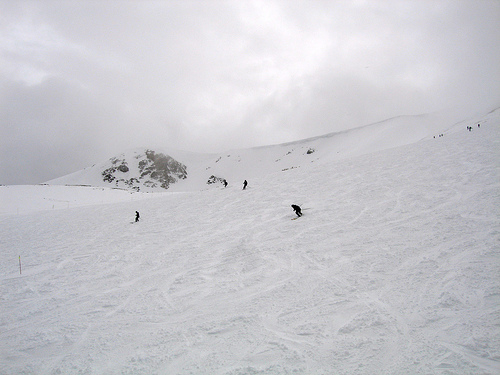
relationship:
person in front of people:
[289, 200, 306, 220] [127, 210, 143, 222]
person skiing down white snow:
[289, 200, 306, 220] [298, 220, 310, 231]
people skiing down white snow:
[127, 210, 143, 222] [298, 220, 310, 231]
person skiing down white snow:
[242, 178, 249, 192] [298, 220, 310, 231]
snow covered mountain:
[220, 239, 242, 254] [131, 154, 191, 186]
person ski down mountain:
[289, 200, 306, 220] [131, 154, 191, 186]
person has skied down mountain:
[289, 200, 306, 220] [131, 154, 191, 186]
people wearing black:
[127, 210, 143, 222] [133, 208, 147, 217]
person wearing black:
[242, 178, 249, 192] [242, 176, 249, 193]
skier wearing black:
[219, 176, 231, 188] [242, 176, 249, 193]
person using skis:
[289, 200, 306, 220] [293, 211, 306, 220]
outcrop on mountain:
[106, 150, 198, 184] [131, 154, 191, 186]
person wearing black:
[289, 200, 306, 220] [290, 201, 304, 216]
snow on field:
[220, 239, 242, 254] [183, 223, 284, 252]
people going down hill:
[127, 210, 143, 222] [92, 265, 191, 317]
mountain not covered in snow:
[131, 154, 191, 186] [220, 239, 242, 254]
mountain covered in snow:
[0, 103, 499, 281] [220, 239, 242, 254]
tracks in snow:
[385, 177, 421, 205] [220, 239, 242, 254]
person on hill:
[289, 200, 306, 220] [92, 265, 191, 317]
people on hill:
[127, 210, 143, 222] [92, 265, 191, 317]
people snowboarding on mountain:
[127, 210, 143, 222] [131, 154, 191, 186]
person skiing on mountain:
[289, 200, 306, 220] [131, 154, 191, 186]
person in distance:
[242, 178, 249, 192] [242, 178, 251, 188]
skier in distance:
[219, 176, 231, 188] [221, 177, 230, 187]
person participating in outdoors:
[289, 200, 306, 220] [289, 201, 303, 217]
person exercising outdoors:
[289, 200, 306, 220] [289, 201, 300, 216]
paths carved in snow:
[103, 230, 123, 244] [220, 239, 242, 254]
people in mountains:
[127, 210, 143, 222] [353, 139, 492, 219]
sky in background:
[14, 4, 484, 95] [250, 19, 459, 89]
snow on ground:
[220, 239, 242, 254] [198, 259, 293, 317]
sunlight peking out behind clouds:
[264, 66, 301, 84] [252, 62, 305, 96]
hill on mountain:
[106, 150, 198, 184] [0, 103, 499, 281]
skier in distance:
[468, 124, 472, 133] [469, 125, 476, 135]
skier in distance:
[474, 119, 483, 129] [478, 122, 485, 132]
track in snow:
[309, 197, 333, 214] [220, 239, 242, 254]